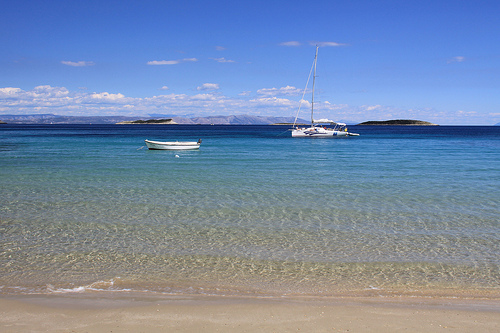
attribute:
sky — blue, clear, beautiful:
[0, 0, 499, 126]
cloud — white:
[147, 59, 179, 65]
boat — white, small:
[143, 136, 202, 152]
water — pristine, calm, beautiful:
[0, 125, 499, 300]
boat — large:
[289, 45, 361, 139]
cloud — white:
[60, 60, 97, 69]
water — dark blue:
[1, 125, 499, 138]